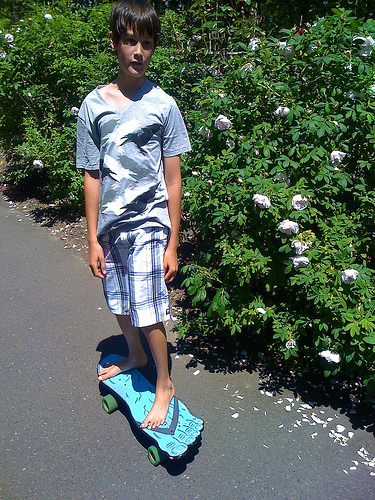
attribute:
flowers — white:
[254, 193, 271, 208]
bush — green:
[195, 25, 372, 372]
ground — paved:
[0, 236, 90, 496]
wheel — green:
[102, 398, 114, 414]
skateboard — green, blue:
[92, 350, 207, 464]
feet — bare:
[98, 356, 173, 427]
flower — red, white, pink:
[210, 87, 220, 92]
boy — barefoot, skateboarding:
[71, 0, 180, 427]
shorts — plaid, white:
[91, 225, 178, 326]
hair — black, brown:
[104, 0, 167, 36]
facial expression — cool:
[125, 45, 149, 72]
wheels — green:
[99, 397, 117, 418]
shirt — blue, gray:
[77, 74, 190, 239]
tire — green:
[100, 390, 121, 415]